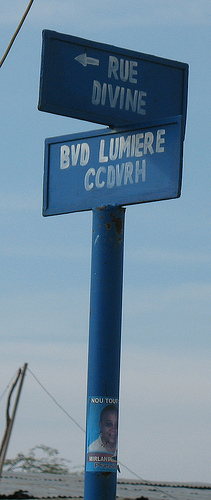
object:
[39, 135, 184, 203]
blue sign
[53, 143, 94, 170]
bvd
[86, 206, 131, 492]
blue pole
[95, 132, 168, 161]
writing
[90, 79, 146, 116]
divine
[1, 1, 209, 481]
sky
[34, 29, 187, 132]
street sign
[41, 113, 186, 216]
street sign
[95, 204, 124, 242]
rusty area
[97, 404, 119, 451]
woman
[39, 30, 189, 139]
top bluesign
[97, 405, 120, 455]
person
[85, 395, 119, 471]
picture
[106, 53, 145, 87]
rue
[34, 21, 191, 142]
sign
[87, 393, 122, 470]
paper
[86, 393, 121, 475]
paper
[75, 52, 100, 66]
arrow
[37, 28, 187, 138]
top sign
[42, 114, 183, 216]
bottom sign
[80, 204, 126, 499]
pole